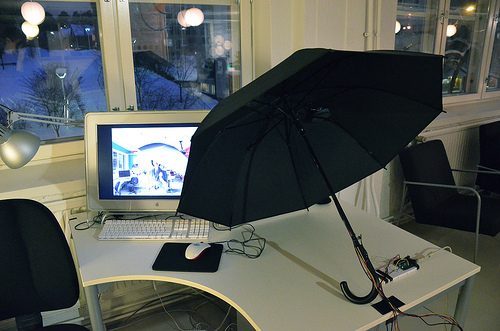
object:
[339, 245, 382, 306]
umbrella handle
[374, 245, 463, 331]
wires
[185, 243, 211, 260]
apple mouse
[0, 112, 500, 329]
experiment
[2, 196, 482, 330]
desk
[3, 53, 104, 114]
snowing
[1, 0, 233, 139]
outside